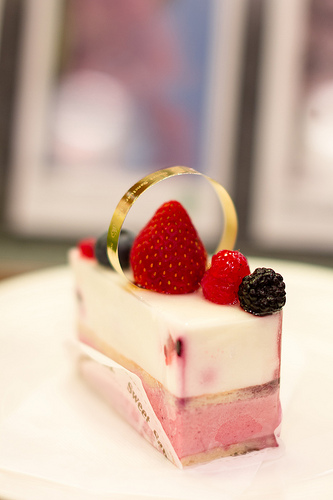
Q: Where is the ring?
A: On a cake.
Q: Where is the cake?
A: On a paper wrapper.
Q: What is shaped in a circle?
A: Gold ring.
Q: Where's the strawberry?
A: On dessert.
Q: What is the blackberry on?
A: Dessert.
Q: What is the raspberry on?
A: Dessert.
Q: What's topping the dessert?
A: Fruits.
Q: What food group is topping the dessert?
A: Fruits.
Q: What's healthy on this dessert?
A: Fruits.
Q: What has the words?
A: Paper.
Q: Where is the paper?
A: Under dessert.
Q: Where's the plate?
A: Under dessert.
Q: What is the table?
A: Dessert.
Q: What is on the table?
A: Dessert.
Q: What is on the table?
A: Sweet.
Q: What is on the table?
A: Fruit.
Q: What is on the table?
A: Food.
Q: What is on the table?
A: Band.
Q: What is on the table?
A: Ring.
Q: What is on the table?
A: Cake.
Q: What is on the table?
A: Cake.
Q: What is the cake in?
A: Wrapping.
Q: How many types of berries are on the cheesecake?
A: 5.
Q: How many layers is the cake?
A: Two.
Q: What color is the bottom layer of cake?
A: Pink.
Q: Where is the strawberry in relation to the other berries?
A: In the middle.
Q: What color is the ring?
A: Gold.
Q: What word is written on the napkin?
A: Sweet.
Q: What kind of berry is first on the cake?
A: A Blackberry.